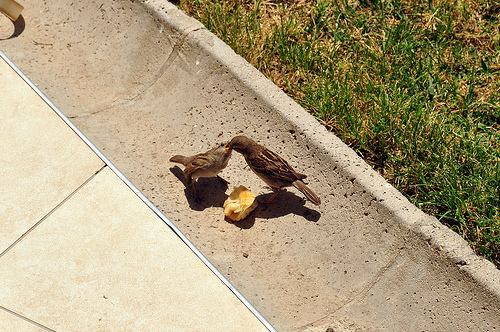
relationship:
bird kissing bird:
[225, 134, 323, 206] [170, 143, 232, 185]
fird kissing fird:
[230, 133, 323, 205] [167, 138, 232, 205]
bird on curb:
[225, 134, 323, 206] [0, 1, 500, 329]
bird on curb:
[168, 140, 236, 207] [0, 1, 500, 329]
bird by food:
[225, 134, 323, 206] [225, 183, 263, 223]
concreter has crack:
[0, 150, 102, 292] [0, 162, 114, 257]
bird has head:
[168, 140, 236, 207] [216, 140, 230, 160]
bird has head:
[225, 134, 323, 206] [224, 132, 251, 152]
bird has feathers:
[222, 131, 327, 212] [252, 158, 301, 177]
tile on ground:
[2, 108, 252, 328] [409, 121, 478, 191]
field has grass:
[335, 30, 470, 171] [331, 54, 467, 156]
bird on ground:
[225, 134, 323, 206] [105, 102, 316, 282]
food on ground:
[225, 187, 270, 224] [171, 124, 312, 249]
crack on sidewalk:
[53, 174, 81, 202] [15, 20, 443, 329]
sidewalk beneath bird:
[61, 58, 393, 308] [228, 135, 320, 202]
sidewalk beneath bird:
[61, 58, 393, 308] [168, 142, 231, 181]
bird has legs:
[225, 134, 323, 206] [262, 183, 295, 204]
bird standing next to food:
[225, 134, 323, 206] [221, 185, 261, 225]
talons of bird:
[259, 188, 284, 209] [225, 134, 323, 206]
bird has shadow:
[168, 138, 236, 188] [164, 164, 227, 213]